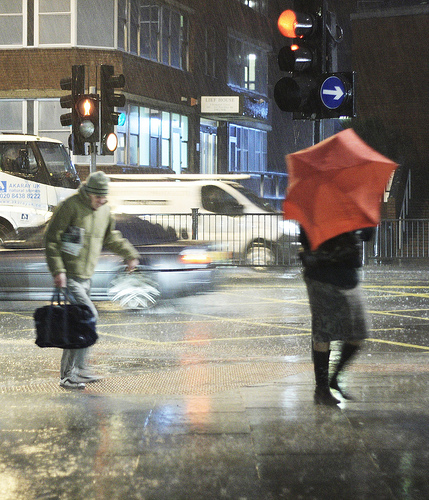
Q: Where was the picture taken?
A: It was taken at the street.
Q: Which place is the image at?
A: It is at the street.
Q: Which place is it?
A: It is a street.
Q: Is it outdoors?
A: Yes, it is outdoors.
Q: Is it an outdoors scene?
A: Yes, it is outdoors.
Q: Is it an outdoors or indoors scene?
A: It is outdoors.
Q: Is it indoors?
A: No, it is outdoors.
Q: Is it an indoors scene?
A: No, it is outdoors.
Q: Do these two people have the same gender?
A: No, they are both male and female.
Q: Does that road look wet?
A: Yes, the road is wet.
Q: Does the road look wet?
A: Yes, the road is wet.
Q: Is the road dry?
A: No, the road is wet.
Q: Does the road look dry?
A: No, the road is wet.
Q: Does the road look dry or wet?
A: The road is wet.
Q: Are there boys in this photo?
A: No, there are no boys.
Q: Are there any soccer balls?
A: No, there are no soccer balls.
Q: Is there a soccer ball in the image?
A: No, there are no soccer balls.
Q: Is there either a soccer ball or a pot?
A: No, there are no soccer balls or pots.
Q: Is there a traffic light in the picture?
A: Yes, there is a traffic light.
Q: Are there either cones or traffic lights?
A: Yes, there is a traffic light.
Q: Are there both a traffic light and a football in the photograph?
A: No, there is a traffic light but no footballs.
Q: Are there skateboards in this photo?
A: No, there are no skateboards.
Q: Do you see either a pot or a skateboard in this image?
A: No, there are no skateboards or pots.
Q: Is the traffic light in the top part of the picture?
A: Yes, the traffic light is in the top of the image.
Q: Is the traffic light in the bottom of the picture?
A: No, the traffic light is in the top of the image.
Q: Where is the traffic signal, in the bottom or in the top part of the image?
A: The traffic signal is in the top of the image.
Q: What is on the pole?
A: The traffic light is on the pole.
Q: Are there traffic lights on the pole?
A: Yes, there is a traffic light on the pole.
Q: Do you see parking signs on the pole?
A: No, there is a traffic light on the pole.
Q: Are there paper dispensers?
A: No, there are no paper dispensers.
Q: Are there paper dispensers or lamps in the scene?
A: No, there are no paper dispensers or lamps.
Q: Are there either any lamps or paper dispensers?
A: No, there are no paper dispensers or lamps.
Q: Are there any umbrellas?
A: Yes, there is an umbrella.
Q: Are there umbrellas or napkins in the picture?
A: Yes, there is an umbrella.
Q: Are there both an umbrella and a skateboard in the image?
A: No, there is an umbrella but no skateboards.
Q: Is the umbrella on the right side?
A: Yes, the umbrella is on the right of the image.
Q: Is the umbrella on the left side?
A: No, the umbrella is on the right of the image.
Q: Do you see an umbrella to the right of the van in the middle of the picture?
A: Yes, there is an umbrella to the right of the van.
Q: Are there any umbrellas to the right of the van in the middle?
A: Yes, there is an umbrella to the right of the van.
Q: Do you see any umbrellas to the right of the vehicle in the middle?
A: Yes, there is an umbrella to the right of the van.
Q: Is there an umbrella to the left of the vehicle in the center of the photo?
A: No, the umbrella is to the right of the van.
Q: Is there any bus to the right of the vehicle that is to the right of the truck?
A: No, there is an umbrella to the right of the van.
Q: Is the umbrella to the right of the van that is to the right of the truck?
A: Yes, the umbrella is to the right of the van.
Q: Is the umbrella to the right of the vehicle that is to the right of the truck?
A: Yes, the umbrella is to the right of the van.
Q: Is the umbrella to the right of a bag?
A: No, the umbrella is to the right of the van.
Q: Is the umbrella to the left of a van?
A: No, the umbrella is to the right of a van.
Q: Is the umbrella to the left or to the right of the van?
A: The umbrella is to the right of the van.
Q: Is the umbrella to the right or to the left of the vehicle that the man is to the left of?
A: The umbrella is to the right of the van.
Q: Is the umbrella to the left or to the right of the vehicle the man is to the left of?
A: The umbrella is to the right of the van.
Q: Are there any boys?
A: No, there are no boys.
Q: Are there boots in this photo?
A: Yes, there are boots.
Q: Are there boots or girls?
A: Yes, there are boots.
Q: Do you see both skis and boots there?
A: No, there are boots but no skis.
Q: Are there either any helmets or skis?
A: No, there are no skis or helmets.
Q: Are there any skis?
A: No, there are no skis.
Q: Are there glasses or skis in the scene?
A: No, there are no skis or glasses.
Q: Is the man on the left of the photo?
A: Yes, the man is on the left of the image.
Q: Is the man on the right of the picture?
A: No, the man is on the left of the image.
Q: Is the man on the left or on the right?
A: The man is on the left of the image.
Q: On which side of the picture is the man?
A: The man is on the left of the image.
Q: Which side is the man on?
A: The man is on the left of the image.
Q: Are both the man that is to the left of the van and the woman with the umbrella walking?
A: Yes, both the man and the woman are walking.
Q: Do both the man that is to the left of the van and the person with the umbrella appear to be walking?
A: Yes, both the man and the woman are walking.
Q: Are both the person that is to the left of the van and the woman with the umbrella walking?
A: Yes, both the man and the woman are walking.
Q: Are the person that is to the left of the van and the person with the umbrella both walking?
A: Yes, both the man and the woman are walking.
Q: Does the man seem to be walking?
A: Yes, the man is walking.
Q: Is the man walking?
A: Yes, the man is walking.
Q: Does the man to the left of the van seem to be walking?
A: Yes, the man is walking.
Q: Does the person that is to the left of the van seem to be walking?
A: Yes, the man is walking.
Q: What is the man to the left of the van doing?
A: The man is walking.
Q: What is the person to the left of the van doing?
A: The man is walking.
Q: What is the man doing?
A: The man is walking.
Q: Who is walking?
A: The man is walking.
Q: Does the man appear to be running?
A: No, the man is walking.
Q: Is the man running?
A: No, the man is walking.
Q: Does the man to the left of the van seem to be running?
A: No, the man is walking.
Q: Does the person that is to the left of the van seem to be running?
A: No, the man is walking.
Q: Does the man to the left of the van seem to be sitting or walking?
A: The man is walking.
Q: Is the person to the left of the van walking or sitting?
A: The man is walking.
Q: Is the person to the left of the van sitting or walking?
A: The man is walking.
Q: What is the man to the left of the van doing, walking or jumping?
A: The man is walking.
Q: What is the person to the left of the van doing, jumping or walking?
A: The man is walking.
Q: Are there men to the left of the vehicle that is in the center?
A: Yes, there is a man to the left of the van.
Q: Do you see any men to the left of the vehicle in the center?
A: Yes, there is a man to the left of the van.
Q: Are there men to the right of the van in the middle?
A: No, the man is to the left of the van.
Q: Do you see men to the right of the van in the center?
A: No, the man is to the left of the van.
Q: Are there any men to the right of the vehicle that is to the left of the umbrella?
A: No, the man is to the left of the van.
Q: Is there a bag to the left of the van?
A: No, there is a man to the left of the van.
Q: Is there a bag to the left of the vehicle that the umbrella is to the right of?
A: No, there is a man to the left of the van.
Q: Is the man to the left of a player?
A: No, the man is to the left of the van.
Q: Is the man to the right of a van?
A: No, the man is to the left of a van.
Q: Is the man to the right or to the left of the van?
A: The man is to the left of the van.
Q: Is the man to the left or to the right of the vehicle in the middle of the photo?
A: The man is to the left of the van.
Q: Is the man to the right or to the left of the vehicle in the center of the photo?
A: The man is to the left of the van.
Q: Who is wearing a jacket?
A: The man is wearing a jacket.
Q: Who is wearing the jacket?
A: The man is wearing a jacket.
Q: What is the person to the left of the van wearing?
A: The man is wearing a jacket.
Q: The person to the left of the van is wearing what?
A: The man is wearing a jacket.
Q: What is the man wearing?
A: The man is wearing a jacket.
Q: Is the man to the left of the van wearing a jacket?
A: Yes, the man is wearing a jacket.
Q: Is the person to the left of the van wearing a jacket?
A: Yes, the man is wearing a jacket.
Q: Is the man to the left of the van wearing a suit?
A: No, the man is wearing a jacket.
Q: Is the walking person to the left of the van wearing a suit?
A: No, the man is wearing a jacket.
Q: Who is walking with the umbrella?
A: The man is walking with the umbrella.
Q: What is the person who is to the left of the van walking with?
A: The man is walking with an umbrella.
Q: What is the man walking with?
A: The man is walking with an umbrella.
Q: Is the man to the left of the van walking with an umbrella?
A: Yes, the man is walking with an umbrella.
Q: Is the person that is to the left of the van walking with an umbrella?
A: Yes, the man is walking with an umbrella.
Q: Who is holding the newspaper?
A: The man is holding the newspaper.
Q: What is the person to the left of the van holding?
A: The man is holding the newspaper.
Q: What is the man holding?
A: The man is holding the newspaper.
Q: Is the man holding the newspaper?
A: Yes, the man is holding the newspaper.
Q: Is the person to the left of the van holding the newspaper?
A: Yes, the man is holding the newspaper.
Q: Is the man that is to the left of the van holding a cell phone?
A: No, the man is holding the newspaper.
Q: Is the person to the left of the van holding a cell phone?
A: No, the man is holding the newspaper.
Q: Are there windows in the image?
A: Yes, there is a window.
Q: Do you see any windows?
A: Yes, there is a window.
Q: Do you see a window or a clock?
A: Yes, there is a window.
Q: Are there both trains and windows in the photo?
A: No, there is a window but no trains.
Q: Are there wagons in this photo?
A: No, there are no wagons.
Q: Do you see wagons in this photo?
A: No, there are no wagons.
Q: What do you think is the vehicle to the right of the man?
A: The vehicle is a van.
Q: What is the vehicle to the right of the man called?
A: The vehicle is a van.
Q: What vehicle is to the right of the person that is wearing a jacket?
A: The vehicle is a van.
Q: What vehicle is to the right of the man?
A: The vehicle is a van.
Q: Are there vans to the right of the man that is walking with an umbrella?
A: Yes, there is a van to the right of the man.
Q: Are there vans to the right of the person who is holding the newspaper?
A: Yes, there is a van to the right of the man.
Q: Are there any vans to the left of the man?
A: No, the van is to the right of the man.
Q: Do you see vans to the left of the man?
A: No, the van is to the right of the man.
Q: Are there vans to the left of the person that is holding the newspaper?
A: No, the van is to the right of the man.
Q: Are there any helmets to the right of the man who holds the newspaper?
A: No, there is a van to the right of the man.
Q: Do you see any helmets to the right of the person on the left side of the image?
A: No, there is a van to the right of the man.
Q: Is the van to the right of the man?
A: Yes, the van is to the right of the man.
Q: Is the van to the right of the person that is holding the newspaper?
A: Yes, the van is to the right of the man.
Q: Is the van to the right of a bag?
A: No, the van is to the right of the man.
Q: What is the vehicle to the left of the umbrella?
A: The vehicle is a van.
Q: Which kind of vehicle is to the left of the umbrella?
A: The vehicle is a van.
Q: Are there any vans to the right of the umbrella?
A: No, the van is to the left of the umbrella.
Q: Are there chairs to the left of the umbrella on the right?
A: No, there is a van to the left of the umbrella.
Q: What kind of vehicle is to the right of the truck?
A: The vehicle is a van.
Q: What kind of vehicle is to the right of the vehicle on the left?
A: The vehicle is a van.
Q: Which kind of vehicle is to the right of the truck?
A: The vehicle is a van.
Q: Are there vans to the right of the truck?
A: Yes, there is a van to the right of the truck.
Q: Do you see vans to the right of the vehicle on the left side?
A: Yes, there is a van to the right of the truck.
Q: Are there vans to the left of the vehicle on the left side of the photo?
A: No, the van is to the right of the truck.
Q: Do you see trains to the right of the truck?
A: No, there is a van to the right of the truck.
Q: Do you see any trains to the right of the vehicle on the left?
A: No, there is a van to the right of the truck.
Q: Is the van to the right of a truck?
A: Yes, the van is to the right of a truck.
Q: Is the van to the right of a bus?
A: No, the van is to the right of a truck.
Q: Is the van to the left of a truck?
A: No, the van is to the right of a truck.